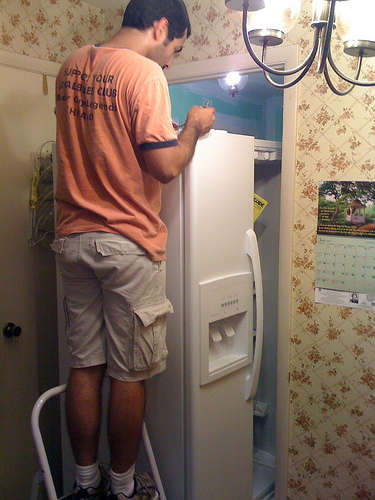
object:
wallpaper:
[0, 0, 375, 500]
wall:
[0, 0, 374, 495]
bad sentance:
[317, 106, 335, 131]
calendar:
[312, 178, 374, 308]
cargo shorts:
[49, 232, 175, 380]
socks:
[71, 457, 98, 488]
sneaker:
[109, 461, 136, 497]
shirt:
[52, 40, 178, 261]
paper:
[254, 193, 268, 223]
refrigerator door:
[179, 129, 265, 500]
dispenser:
[198, 270, 253, 387]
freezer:
[51, 129, 263, 500]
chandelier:
[218, 0, 374, 106]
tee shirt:
[52, 40, 178, 264]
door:
[182, 131, 263, 499]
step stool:
[29, 382, 165, 499]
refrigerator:
[51, 128, 264, 500]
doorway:
[162, 57, 301, 500]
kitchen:
[1, 0, 372, 500]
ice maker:
[203, 308, 252, 377]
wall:
[300, 120, 373, 381]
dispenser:
[208, 308, 247, 373]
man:
[52, 1, 214, 498]